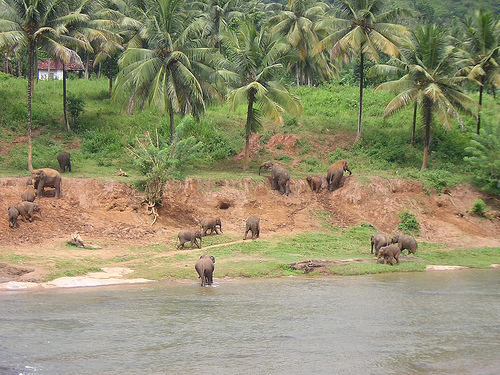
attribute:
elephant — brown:
[194, 255, 215, 286]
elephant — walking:
[198, 215, 223, 234]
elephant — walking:
[174, 225, 204, 249]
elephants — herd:
[177, 205, 268, 292]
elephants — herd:
[254, 143, 363, 208]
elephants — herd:
[365, 219, 425, 271]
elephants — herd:
[11, 145, 79, 228]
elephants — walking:
[198, 164, 419, 299]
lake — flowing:
[0, 265, 497, 374]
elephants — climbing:
[253, 146, 355, 202]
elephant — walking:
[257, 159, 291, 193]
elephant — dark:
[175, 227, 207, 250]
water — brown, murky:
[0, 267, 499, 374]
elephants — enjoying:
[327, 155, 353, 195]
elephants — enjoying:
[264, 161, 360, 205]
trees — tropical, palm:
[133, 9, 298, 159]